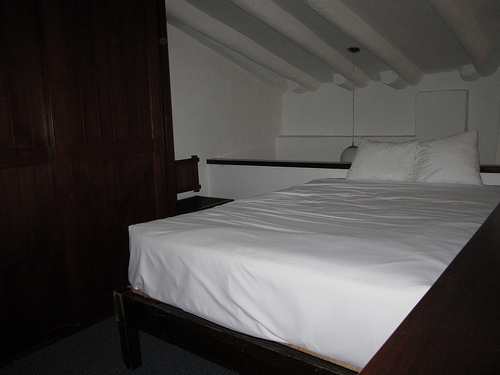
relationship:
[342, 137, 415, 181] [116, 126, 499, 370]
pillow on bed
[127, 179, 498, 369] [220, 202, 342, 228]
sheets has wrinkles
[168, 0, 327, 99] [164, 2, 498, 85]
light on ceiling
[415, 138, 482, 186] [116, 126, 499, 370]
pillow on bed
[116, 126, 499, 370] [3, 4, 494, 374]
bed in room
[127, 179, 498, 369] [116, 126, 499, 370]
sheets on bed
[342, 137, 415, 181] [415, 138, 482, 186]
pillow next to pillow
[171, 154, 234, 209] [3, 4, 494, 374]
chair in room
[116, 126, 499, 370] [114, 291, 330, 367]
bed has bed frame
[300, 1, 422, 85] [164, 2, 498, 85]
light on ceiling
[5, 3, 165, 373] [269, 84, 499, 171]
paneling against wall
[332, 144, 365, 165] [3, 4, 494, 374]
light in room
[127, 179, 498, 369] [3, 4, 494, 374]
sheets in room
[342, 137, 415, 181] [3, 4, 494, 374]
pillow in room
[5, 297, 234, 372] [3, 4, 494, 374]
carpet in room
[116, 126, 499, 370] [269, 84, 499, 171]
bed near wall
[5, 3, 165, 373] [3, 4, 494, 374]
paneling in room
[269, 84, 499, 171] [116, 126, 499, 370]
wall behind bed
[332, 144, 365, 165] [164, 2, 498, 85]
light hanging from ceiling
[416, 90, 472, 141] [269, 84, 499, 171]
picture on wall